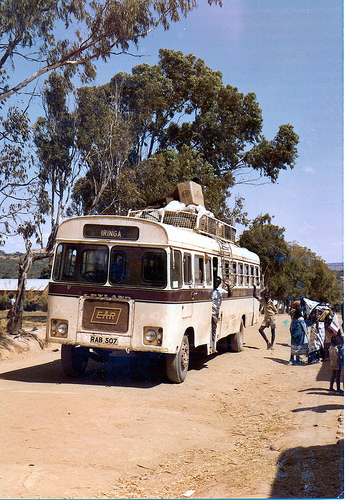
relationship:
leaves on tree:
[306, 262, 315, 274] [293, 247, 329, 300]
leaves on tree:
[322, 275, 337, 298] [95, 75, 217, 224]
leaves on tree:
[237, 119, 256, 134] [49, 21, 325, 296]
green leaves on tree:
[132, 165, 169, 192] [73, 50, 296, 213]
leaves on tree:
[54, 82, 140, 160] [21, 44, 236, 337]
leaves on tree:
[73, 48, 299, 225] [74, 46, 299, 224]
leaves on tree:
[113, 130, 135, 148] [0, 0, 342, 333]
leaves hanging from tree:
[159, 159, 189, 173] [42, 43, 299, 223]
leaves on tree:
[235, 210, 290, 289] [240, 208, 290, 309]